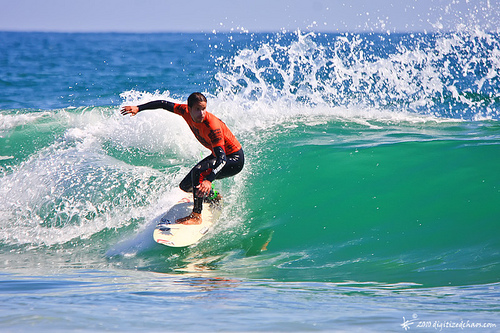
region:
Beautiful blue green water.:
[263, 134, 483, 229]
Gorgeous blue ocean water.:
[11, 35, 212, 85]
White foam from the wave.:
[222, 18, 481, 98]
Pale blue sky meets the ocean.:
[27, 7, 179, 42]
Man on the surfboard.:
[117, 65, 250, 295]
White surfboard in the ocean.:
[148, 189, 223, 255]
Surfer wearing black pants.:
[171, 145, 251, 219]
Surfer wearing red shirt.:
[165, 83, 240, 167]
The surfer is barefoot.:
[167, 190, 226, 231]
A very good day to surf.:
[62, 23, 369, 188]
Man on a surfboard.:
[106, 59, 291, 281]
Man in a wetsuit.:
[117, 60, 357, 289]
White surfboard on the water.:
[128, 173, 283, 297]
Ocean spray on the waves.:
[61, 94, 374, 319]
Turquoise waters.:
[164, 130, 444, 319]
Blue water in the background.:
[52, 30, 179, 133]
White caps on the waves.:
[85, 81, 257, 220]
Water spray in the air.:
[233, 38, 483, 130]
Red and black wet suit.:
[111, 78, 258, 239]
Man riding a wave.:
[77, 61, 320, 322]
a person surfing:
[122, 92, 240, 223]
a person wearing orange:
[121, 96, 247, 156]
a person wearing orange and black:
[117, 81, 244, 225]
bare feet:
[180, 210, 212, 225]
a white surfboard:
[159, 172, 231, 252]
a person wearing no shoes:
[120, 93, 253, 255]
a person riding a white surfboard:
[124, 95, 244, 244]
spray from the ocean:
[214, 30, 494, 117]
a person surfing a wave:
[33, 67, 443, 257]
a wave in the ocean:
[259, 67, 494, 282]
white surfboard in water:
[151, 163, 243, 247]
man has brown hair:
[119, 93, 244, 228]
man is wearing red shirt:
[120, 91, 244, 223]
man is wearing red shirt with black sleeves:
[122, 95, 244, 223]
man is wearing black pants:
[120, 91, 245, 223]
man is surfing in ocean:
[119, 89, 251, 246]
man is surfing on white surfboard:
[118, 93, 250, 247]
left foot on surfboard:
[172, 211, 200, 225]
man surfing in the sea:
[122, 91, 253, 246]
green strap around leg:
[205, 188, 217, 200]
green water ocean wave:
[397, 156, 486, 280]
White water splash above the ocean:
[261, 46, 340, 105]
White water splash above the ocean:
[435, 11, 498, 131]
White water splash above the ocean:
[45, 126, 152, 249]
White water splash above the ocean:
[95, 94, 191, 155]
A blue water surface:
[37, 36, 162, 89]